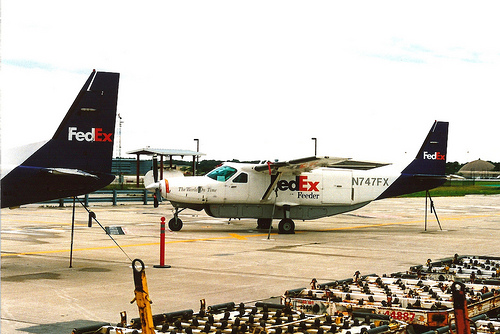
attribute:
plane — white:
[124, 133, 458, 236]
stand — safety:
[130, 208, 206, 288]